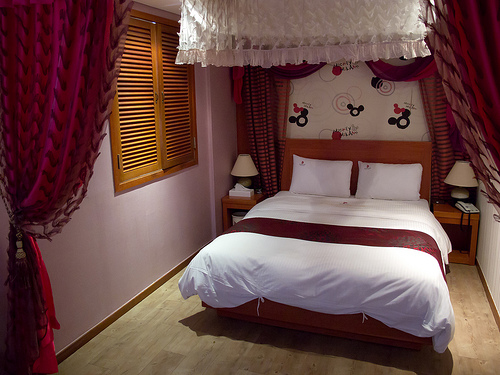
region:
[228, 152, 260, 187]
Small lamp on nightstand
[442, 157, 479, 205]
Small lamp on nightstand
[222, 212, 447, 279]
Red blanket over white comforter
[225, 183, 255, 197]
White tissue box next to bed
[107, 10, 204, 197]
Wooden window next to bed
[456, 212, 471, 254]
Black cord attached to telephone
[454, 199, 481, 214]
White phone in front of lamp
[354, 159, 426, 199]
White pillow leaning on headboard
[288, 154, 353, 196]
White pillow next to white pillow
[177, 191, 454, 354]
White comforter on bed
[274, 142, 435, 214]
two white pillows on the bed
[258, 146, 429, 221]
two white pillows on the bed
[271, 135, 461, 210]
two white pillows on the bed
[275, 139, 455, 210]
two white pillows on the bed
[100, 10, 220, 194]
the window is closed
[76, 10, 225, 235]
the window is closed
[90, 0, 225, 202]
the window is closed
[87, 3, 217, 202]
the window is closed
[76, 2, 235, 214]
the window is closed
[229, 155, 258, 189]
lamp on the side table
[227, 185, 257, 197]
a box of tissues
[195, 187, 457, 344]
a white bed spread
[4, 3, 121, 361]
red decorative curtains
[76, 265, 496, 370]
light hardwood floors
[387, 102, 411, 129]
a character head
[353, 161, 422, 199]
white pillow case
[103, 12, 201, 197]
wood framed window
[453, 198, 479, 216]
a telephone on the night table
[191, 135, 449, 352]
a queen size bed in a bedroom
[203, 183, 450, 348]
a white comforter is on the bed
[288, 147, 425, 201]
white pillows are on the bed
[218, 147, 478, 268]
a bedside table is on each side of the bed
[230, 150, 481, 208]
white lamps are on each side of the bed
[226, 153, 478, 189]
white shades are on each side of the bed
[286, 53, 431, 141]
the headboard of the bed has mickey mouse ears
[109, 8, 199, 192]
wood shutters are on the window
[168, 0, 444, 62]
a valance is over the bed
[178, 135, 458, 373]
A made bed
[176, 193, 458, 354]
White cotton comforter with red stripe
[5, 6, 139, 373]
Red lacey curtains hanging in a doorway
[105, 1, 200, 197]
Brown wood shutters closed on a window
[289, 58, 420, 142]
Mickey mouse head patterened wallpaper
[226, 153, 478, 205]
Two cream colored table lamps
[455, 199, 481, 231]
A plug in telephone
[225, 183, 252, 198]
Box of tissues on a nightstand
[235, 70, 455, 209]
Red and black striped curtains next to a bed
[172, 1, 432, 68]
White lacey drapes hanging from a ceiling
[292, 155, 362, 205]
A pillow on the bed.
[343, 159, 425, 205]
A pillow on the bed.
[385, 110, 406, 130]
A decal on the wall.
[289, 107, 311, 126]
A decal on the wall.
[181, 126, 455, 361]
bed with a white comforter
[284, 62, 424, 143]
mouse ears painted on a wall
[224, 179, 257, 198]
box of tissues next to bed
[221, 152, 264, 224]
nightstand with lamp and tissues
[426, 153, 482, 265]
nightstand with lamp and phone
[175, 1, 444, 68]
white canopy above bed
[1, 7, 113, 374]
burgandy curtain with a tieback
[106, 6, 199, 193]
wood blinds on a window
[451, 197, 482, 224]
white landline phone next to bed